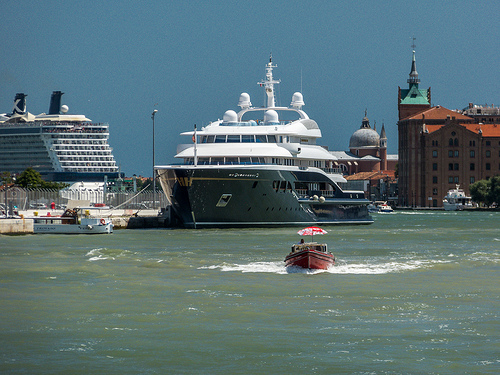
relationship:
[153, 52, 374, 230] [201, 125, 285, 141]
boat has bridge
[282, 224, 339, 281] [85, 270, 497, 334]
boat on water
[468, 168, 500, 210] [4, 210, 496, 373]
trees beside water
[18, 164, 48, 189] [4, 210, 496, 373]
trees beside water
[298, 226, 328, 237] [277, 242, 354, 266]
umbrella on boat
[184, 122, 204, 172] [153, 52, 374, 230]
flag on boat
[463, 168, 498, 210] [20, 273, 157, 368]
trees next to water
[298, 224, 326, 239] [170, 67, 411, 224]
umbrella on boat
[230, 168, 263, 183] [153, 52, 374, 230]
writing on boat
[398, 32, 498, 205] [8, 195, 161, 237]
building along shore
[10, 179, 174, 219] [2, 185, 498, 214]
metal fence along shoreline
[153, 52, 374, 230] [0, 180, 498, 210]
boat docked along shore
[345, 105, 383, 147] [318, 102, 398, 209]
dome on building